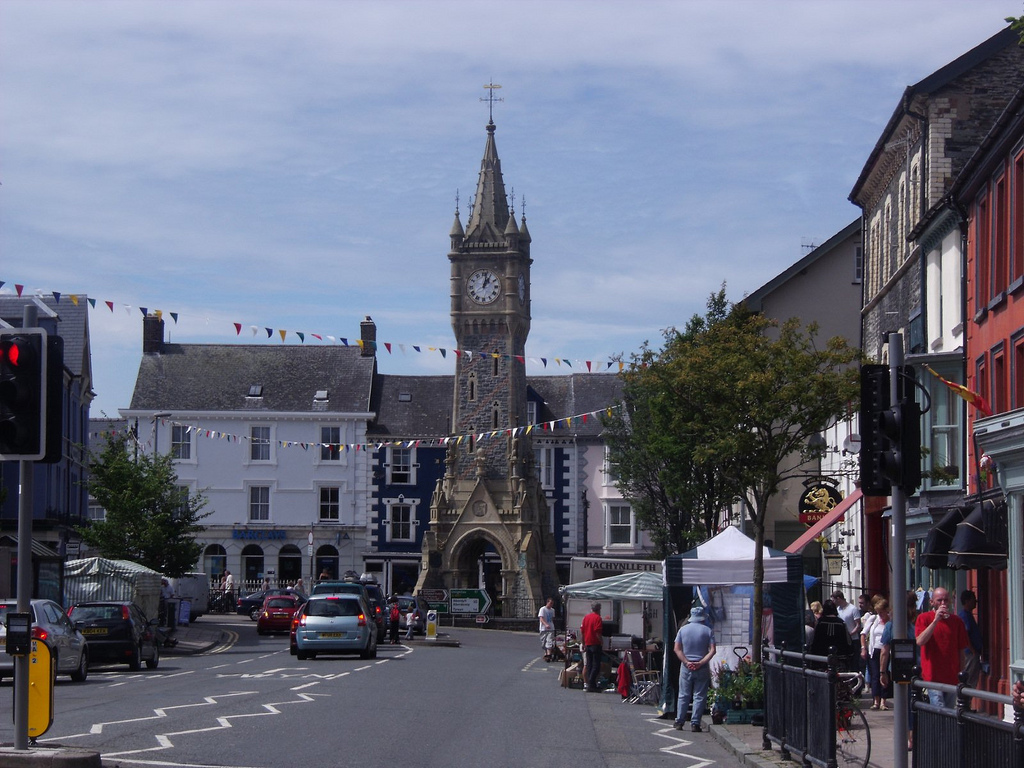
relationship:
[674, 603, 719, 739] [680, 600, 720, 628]
man wearing hat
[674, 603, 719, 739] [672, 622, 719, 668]
man wearing blue shirt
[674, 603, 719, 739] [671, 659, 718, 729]
man wearing pants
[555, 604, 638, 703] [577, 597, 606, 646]
man wearing shirt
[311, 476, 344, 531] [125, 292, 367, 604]
window on building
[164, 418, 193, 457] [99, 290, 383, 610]
window on building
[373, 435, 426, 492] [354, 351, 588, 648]
window on building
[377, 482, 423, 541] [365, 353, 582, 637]
window on building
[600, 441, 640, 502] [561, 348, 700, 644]
window on building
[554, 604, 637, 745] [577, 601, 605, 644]
man wearing shirt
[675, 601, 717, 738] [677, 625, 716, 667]
man in blue shirt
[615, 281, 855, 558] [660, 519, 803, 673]
green tree over white/blue tent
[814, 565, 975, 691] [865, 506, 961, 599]
people standing in front of store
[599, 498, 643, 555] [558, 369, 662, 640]
window on building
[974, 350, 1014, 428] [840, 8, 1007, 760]
window has building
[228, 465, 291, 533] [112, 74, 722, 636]
window on building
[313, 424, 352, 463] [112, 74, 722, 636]
window on building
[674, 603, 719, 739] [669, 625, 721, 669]
man with arms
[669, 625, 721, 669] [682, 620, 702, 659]
arms behind back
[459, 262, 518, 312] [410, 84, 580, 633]
white clock on tower